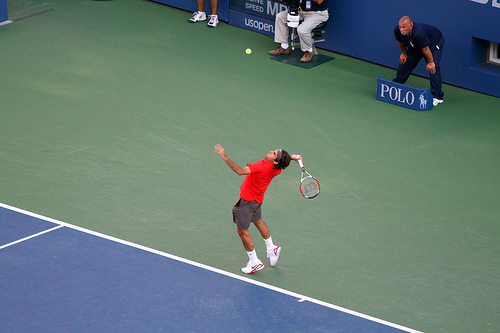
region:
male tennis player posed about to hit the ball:
[201, 132, 336, 296]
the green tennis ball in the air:
[240, 44, 256, 59]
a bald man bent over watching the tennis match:
[381, 8, 452, 113]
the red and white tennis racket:
[292, 154, 323, 204]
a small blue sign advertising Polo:
[374, 73, 436, 115]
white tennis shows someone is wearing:
[182, 10, 225, 32]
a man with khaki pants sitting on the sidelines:
[261, 5, 343, 67]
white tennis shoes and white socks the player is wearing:
[238, 238, 287, 273]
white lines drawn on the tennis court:
[17, 204, 114, 254]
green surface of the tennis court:
[20, 48, 173, 188]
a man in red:
[225, 212, 291, 325]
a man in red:
[206, 106, 270, 279]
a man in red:
[216, 30, 308, 322]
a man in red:
[235, 106, 315, 297]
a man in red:
[188, 110, 295, 329]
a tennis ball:
[235, 43, 259, 59]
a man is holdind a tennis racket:
[290, 153, 329, 205]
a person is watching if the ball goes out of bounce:
[385, 13, 453, 109]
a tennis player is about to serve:
[212, 30, 320, 287]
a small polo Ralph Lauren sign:
[359, 72, 439, 119]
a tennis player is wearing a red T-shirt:
[212, 133, 339, 290]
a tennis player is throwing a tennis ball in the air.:
[197, 34, 324, 278]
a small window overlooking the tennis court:
[474, 42, 499, 78]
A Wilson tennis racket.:
[294, 148, 329, 208]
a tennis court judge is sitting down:
[271, 0, 337, 62]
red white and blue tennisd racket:
[290, 157, 345, 214]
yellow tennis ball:
[237, 37, 269, 62]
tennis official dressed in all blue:
[380, 6, 465, 105]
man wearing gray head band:
[263, 134, 295, 167]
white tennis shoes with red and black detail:
[238, 261, 274, 284]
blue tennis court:
[46, 250, 132, 313]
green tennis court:
[59, 53, 164, 179]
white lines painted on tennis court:
[11, 188, 178, 304]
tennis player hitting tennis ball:
[195, 112, 352, 299]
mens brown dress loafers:
[266, 38, 323, 75]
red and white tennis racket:
[294, 150, 327, 216]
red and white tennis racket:
[291, 152, 317, 243]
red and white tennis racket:
[283, 122, 325, 206]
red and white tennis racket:
[286, 142, 343, 224]